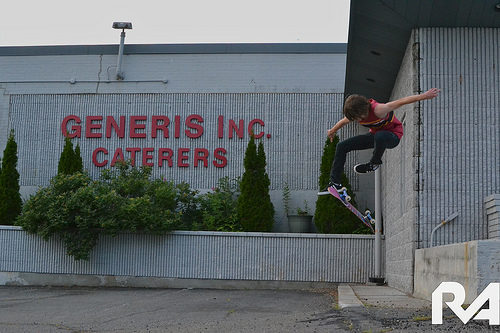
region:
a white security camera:
[112, 18, 150, 85]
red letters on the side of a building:
[59, 110, 273, 171]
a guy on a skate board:
[318, 85, 444, 234]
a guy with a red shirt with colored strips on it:
[326, 85, 443, 138]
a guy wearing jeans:
[325, 85, 442, 193]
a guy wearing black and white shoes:
[315, 88, 445, 205]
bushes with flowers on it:
[14, 165, 204, 258]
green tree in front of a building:
[234, 134, 281, 231]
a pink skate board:
[322, 184, 384, 231]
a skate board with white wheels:
[324, 183, 387, 234]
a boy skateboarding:
[262, 67, 436, 236]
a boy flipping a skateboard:
[290, 56, 451, 227]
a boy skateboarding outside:
[254, 57, 428, 246]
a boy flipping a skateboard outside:
[277, 68, 499, 291]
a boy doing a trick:
[272, 57, 469, 265]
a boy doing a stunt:
[282, 57, 494, 274]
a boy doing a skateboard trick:
[272, 71, 447, 284]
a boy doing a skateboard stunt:
[254, 61, 496, 299]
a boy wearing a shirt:
[259, 53, 481, 255]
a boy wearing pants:
[312, 62, 495, 322]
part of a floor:
[226, 295, 252, 322]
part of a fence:
[234, 237, 264, 267]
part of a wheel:
[346, 200, 383, 238]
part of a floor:
[246, 309, 266, 330]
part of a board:
[331, 167, 361, 229]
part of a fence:
[253, 217, 283, 250]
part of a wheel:
[361, 200, 385, 227]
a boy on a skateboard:
[272, 46, 460, 293]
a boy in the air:
[229, 27, 465, 289]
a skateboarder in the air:
[265, 52, 447, 315]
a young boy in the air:
[259, 35, 471, 280]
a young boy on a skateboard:
[275, 42, 486, 287]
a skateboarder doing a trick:
[280, 60, 445, 282]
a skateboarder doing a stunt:
[239, 52, 457, 294]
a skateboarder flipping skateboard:
[253, 22, 495, 318]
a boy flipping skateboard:
[229, 60, 441, 323]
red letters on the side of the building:
[51, 100, 276, 182]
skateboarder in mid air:
[321, 74, 439, 247]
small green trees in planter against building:
[236, 131, 278, 242]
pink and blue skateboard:
[319, 182, 382, 239]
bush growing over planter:
[19, 176, 142, 270]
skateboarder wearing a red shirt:
[353, 94, 402, 138]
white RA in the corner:
[423, 274, 497, 329]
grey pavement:
[84, 289, 188, 331]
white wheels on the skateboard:
[362, 207, 375, 225]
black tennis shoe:
[353, 159, 381, 176]